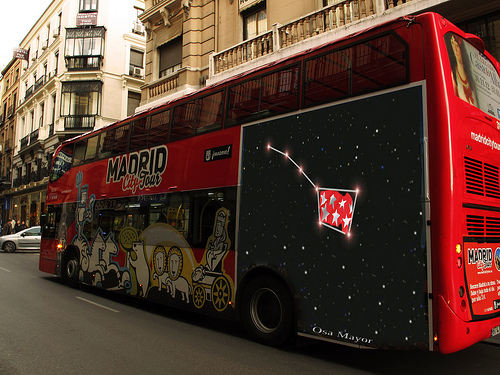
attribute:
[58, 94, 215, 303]
bus — downtown, red, double decker, double, tour, black, double deckered, big, side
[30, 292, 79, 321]
street — stretched, grey, concrete, city, madrid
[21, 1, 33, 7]
sky — day, overcast, night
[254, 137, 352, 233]
dipper — red, big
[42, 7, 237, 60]
buildings — tan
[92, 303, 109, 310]
line — white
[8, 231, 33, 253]
car — silver, driving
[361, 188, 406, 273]
advertisement — black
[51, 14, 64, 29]
curtains — white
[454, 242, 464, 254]
light — on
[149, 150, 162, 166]
writing — black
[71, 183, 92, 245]
gladiator — blue